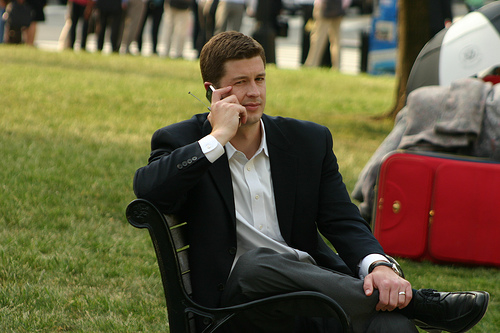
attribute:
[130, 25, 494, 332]
man — sitting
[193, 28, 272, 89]
hair — brown, styled, short, neat, dry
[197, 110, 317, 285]
shirt — white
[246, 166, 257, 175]
button — white, round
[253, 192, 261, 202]
button — round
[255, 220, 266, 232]
button — white, round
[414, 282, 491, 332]
shoe — black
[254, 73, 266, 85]
eye — open